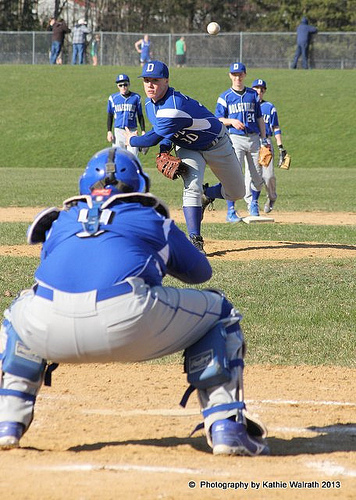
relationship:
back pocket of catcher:
[103, 313, 151, 356] [1, 142, 274, 459]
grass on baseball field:
[0, 64, 356, 212] [0, 166, 354, 498]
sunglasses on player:
[118, 82, 127, 87] [106, 73, 149, 158]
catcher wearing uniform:
[0, 146, 271, 458] [11, 186, 250, 442]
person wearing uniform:
[118, 60, 247, 257] [102, 63, 149, 191]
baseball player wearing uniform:
[214, 62, 273, 224] [211, 56, 268, 227]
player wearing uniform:
[249, 78, 287, 211] [244, 73, 290, 216]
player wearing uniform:
[106, 73, 149, 158] [124, 50, 248, 264]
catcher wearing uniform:
[0, 146, 271, 458] [0, 146, 287, 460]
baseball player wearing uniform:
[214, 62, 273, 224] [214, 88, 267, 198]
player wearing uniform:
[243, 78, 291, 214] [131, 96, 248, 206]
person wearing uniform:
[118, 60, 247, 257] [256, 97, 285, 192]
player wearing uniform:
[105, 74, 147, 163] [11, 186, 250, 442]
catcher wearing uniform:
[0, 146, 271, 458] [101, 89, 145, 156]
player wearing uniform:
[106, 73, 149, 158] [106, 92, 144, 157]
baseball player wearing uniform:
[209, 59, 270, 143] [218, 87, 260, 137]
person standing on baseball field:
[175, 36, 187, 68] [0, 61, 356, 500]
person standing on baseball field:
[137, 29, 151, 64] [0, 61, 356, 500]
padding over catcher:
[22, 201, 60, 245] [1, 142, 274, 459]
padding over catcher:
[61, 191, 170, 219] [1, 142, 274, 459]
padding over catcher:
[73, 193, 115, 240] [1, 142, 274, 459]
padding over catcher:
[183, 316, 232, 399] [1, 142, 274, 459]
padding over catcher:
[1, 318, 48, 380] [1, 142, 274, 459]